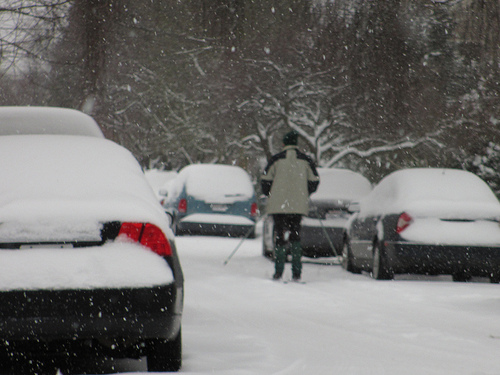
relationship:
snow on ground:
[274, 295, 329, 346] [340, 285, 497, 374]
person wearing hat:
[259, 128, 322, 281] [281, 129, 300, 148]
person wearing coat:
[259, 131, 320, 282] [252, 150, 322, 222]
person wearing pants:
[259, 131, 320, 282] [264, 219, 304, 269]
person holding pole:
[259, 128, 322, 281] [299, 186, 351, 266]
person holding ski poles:
[259, 128, 322, 281] [220, 217, 260, 268]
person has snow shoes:
[259, 131, 320, 282] [257, 270, 315, 288]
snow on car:
[2, 134, 172, 283] [6, 134, 186, 373]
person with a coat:
[259, 131, 320, 282] [257, 148, 318, 218]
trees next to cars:
[6, 6, 495, 209] [141, 152, 497, 277]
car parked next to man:
[341, 166, 499, 283] [255, 128, 327, 284]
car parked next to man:
[263, 166, 372, 260] [255, 128, 327, 284]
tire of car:
[335, 228, 356, 262] [344, 162, 499, 282]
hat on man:
[279, 126, 302, 149] [255, 128, 327, 284]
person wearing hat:
[259, 131, 320, 282] [279, 124, 299, 145]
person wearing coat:
[259, 128, 322, 281] [258, 145, 321, 211]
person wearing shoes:
[259, 128, 322, 281] [269, 245, 304, 279]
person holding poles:
[259, 128, 322, 281] [220, 204, 348, 274]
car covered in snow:
[344, 162, 499, 282] [344, 167, 498, 243]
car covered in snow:
[258, 163, 374, 267] [309, 166, 371, 206]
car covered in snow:
[166, 161, 259, 237] [165, 162, 253, 202]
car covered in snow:
[6, 134, 186, 373] [1, 240, 174, 293]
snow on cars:
[1, 103, 498, 291] [0, 103, 499, 373]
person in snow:
[259, 128, 322, 281] [176, 233, 496, 373]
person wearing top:
[259, 128, 322, 281] [259, 146, 320, 212]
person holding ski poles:
[259, 131, 320, 282] [220, 209, 346, 267]